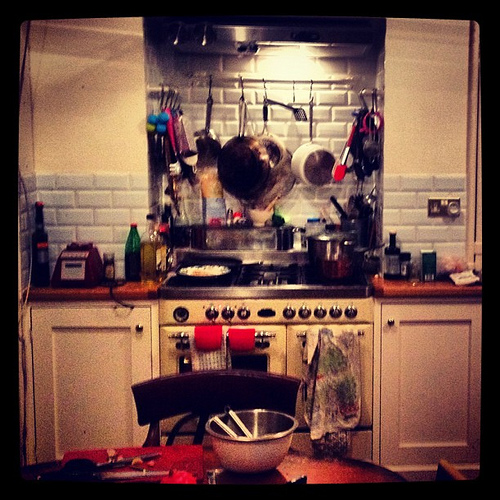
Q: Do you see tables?
A: Yes, there is a table.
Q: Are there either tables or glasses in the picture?
A: Yes, there is a table.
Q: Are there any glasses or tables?
A: Yes, there is a table.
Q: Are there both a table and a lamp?
A: No, there is a table but no lamps.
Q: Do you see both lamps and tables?
A: No, there is a table but no lamps.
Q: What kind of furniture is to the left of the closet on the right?
A: The piece of furniture is a table.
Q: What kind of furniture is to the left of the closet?
A: The piece of furniture is a table.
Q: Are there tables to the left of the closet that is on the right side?
A: Yes, there is a table to the left of the closet.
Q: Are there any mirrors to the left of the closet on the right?
A: No, there is a table to the left of the closet.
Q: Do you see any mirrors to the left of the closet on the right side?
A: No, there is a table to the left of the closet.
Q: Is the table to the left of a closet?
A: Yes, the table is to the left of a closet.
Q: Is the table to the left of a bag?
A: No, the table is to the left of a closet.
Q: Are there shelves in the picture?
A: No, there are no shelves.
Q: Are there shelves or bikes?
A: No, there are no shelves or bikes.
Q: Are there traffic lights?
A: No, there are no traffic lights.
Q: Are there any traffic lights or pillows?
A: No, there are no traffic lights or pillows.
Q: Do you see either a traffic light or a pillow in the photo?
A: No, there are no traffic lights or pillows.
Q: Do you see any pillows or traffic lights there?
A: No, there are no traffic lights or pillows.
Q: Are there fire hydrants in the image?
A: No, there are no fire hydrants.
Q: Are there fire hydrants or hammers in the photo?
A: No, there are no fire hydrants or hammers.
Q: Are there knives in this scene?
A: No, there are no knives.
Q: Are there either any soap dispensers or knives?
A: No, there are no knives or soap dispensers.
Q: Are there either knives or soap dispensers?
A: No, there are no knives or soap dispensers.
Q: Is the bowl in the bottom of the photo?
A: Yes, the bowl is in the bottom of the image.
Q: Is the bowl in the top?
A: No, the bowl is in the bottom of the image.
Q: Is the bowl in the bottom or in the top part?
A: The bowl is in the bottom of the image.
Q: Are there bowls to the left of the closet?
A: Yes, there is a bowl to the left of the closet.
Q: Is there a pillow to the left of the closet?
A: No, there is a bowl to the left of the closet.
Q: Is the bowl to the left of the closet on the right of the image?
A: Yes, the bowl is to the left of the closet.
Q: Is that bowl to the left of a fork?
A: No, the bowl is to the left of the closet.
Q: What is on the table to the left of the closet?
A: The bowl is on the table.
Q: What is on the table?
A: The bowl is on the table.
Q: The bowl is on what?
A: The bowl is on the table.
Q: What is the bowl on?
A: The bowl is on the table.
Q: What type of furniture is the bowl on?
A: The bowl is on the table.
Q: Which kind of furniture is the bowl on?
A: The bowl is on the table.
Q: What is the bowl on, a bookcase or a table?
A: The bowl is on a table.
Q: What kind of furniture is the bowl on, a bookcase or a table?
A: The bowl is on a table.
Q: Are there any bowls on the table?
A: Yes, there is a bowl on the table.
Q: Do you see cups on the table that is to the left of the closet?
A: No, there is a bowl on the table.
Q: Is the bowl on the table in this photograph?
A: Yes, the bowl is on the table.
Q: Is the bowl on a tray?
A: No, the bowl is on the table.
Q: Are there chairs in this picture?
A: Yes, there is a chair.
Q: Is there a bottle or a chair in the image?
A: Yes, there is a chair.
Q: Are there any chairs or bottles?
A: Yes, there is a chair.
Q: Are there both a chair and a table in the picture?
A: Yes, there are both a chair and a table.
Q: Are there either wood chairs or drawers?
A: Yes, there is a wood chair.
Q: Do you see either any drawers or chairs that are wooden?
A: Yes, the chair is wooden.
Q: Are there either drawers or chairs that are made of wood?
A: Yes, the chair is made of wood.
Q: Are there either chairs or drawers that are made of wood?
A: Yes, the chair is made of wood.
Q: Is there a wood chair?
A: Yes, there is a chair that is made of wood.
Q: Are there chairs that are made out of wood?
A: Yes, there is a chair that is made of wood.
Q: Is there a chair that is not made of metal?
A: Yes, there is a chair that is made of wood.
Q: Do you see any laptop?
A: No, there are no laptops.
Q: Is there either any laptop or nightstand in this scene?
A: No, there are no laptops or nightstands.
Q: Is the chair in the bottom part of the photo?
A: Yes, the chair is in the bottom of the image.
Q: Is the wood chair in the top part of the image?
A: No, the chair is in the bottom of the image.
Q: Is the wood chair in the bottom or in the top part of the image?
A: The chair is in the bottom of the image.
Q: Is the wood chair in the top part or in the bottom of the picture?
A: The chair is in the bottom of the image.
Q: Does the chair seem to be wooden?
A: Yes, the chair is wooden.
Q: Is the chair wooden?
A: Yes, the chair is wooden.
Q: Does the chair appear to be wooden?
A: Yes, the chair is wooden.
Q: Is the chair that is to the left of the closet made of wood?
A: Yes, the chair is made of wood.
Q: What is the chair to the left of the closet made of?
A: The chair is made of wood.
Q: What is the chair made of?
A: The chair is made of wood.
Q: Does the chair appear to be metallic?
A: No, the chair is wooden.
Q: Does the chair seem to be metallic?
A: No, the chair is wooden.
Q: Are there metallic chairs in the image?
A: No, there is a chair but it is wooden.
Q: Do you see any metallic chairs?
A: No, there is a chair but it is wooden.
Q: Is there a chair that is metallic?
A: No, there is a chair but it is wooden.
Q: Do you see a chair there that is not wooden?
A: No, there is a chair but it is wooden.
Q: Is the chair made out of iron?
A: No, the chair is made of wood.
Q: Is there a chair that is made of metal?
A: No, there is a chair but it is made of wood.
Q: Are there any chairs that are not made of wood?
A: No, there is a chair but it is made of wood.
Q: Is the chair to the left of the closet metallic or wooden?
A: The chair is wooden.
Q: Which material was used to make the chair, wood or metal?
A: The chair is made of wood.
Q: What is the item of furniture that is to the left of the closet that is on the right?
A: The piece of furniture is a chair.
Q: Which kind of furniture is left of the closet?
A: The piece of furniture is a chair.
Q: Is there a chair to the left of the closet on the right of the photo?
A: Yes, there is a chair to the left of the closet.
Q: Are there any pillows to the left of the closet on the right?
A: No, there is a chair to the left of the closet.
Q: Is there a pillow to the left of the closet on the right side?
A: No, there is a chair to the left of the closet.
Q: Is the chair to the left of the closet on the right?
A: Yes, the chair is to the left of the closet.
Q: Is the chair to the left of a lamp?
A: No, the chair is to the left of the closet.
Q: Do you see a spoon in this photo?
A: Yes, there is a spoon.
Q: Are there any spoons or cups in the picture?
A: Yes, there is a spoon.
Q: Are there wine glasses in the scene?
A: No, there are no wine glasses.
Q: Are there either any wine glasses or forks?
A: No, there are no wine glasses or forks.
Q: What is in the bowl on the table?
A: The spoon is in the bowl.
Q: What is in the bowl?
A: The spoon is in the bowl.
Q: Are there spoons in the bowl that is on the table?
A: Yes, there is a spoon in the bowl.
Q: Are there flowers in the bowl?
A: No, there is a spoon in the bowl.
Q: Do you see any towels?
A: Yes, there is a towel.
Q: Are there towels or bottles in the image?
A: Yes, there is a towel.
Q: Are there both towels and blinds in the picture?
A: No, there is a towel but no blinds.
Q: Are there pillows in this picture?
A: No, there are no pillows.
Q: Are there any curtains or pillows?
A: No, there are no pillows or curtains.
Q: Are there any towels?
A: Yes, there is a towel.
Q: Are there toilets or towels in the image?
A: Yes, there is a towel.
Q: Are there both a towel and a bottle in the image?
A: Yes, there are both a towel and a bottle.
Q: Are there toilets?
A: No, there are no toilets.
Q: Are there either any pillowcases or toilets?
A: No, there are no toilets or pillowcases.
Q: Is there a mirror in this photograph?
A: No, there are no mirrors.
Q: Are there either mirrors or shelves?
A: No, there are no mirrors or shelves.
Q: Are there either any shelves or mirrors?
A: No, there are no mirrors or shelves.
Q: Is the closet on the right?
A: Yes, the closet is on the right of the image.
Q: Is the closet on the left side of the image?
A: No, the closet is on the right of the image.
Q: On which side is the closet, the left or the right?
A: The closet is on the right of the image.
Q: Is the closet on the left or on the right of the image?
A: The closet is on the right of the image.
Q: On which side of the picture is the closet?
A: The closet is on the right of the image.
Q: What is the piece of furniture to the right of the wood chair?
A: The piece of furniture is a closet.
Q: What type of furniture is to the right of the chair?
A: The piece of furniture is a closet.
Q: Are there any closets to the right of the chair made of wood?
A: Yes, there is a closet to the right of the chair.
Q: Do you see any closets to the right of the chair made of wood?
A: Yes, there is a closet to the right of the chair.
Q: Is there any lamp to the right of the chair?
A: No, there is a closet to the right of the chair.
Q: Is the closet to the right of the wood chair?
A: Yes, the closet is to the right of the chair.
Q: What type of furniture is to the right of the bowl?
A: The piece of furniture is a closet.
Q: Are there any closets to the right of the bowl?
A: Yes, there is a closet to the right of the bowl.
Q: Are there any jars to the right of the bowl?
A: No, there is a closet to the right of the bowl.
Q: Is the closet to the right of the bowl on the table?
A: Yes, the closet is to the right of the bowl.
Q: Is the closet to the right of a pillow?
A: No, the closet is to the right of the bowl.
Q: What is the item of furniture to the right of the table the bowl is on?
A: The piece of furniture is a closet.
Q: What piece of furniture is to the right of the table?
A: The piece of furniture is a closet.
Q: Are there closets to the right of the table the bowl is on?
A: Yes, there is a closet to the right of the table.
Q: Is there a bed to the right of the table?
A: No, there is a closet to the right of the table.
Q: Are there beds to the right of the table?
A: No, there is a closet to the right of the table.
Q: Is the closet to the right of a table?
A: Yes, the closet is to the right of a table.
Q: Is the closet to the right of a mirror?
A: No, the closet is to the right of a table.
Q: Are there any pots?
A: Yes, there is a pot.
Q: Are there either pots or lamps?
A: Yes, there is a pot.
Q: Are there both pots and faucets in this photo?
A: No, there is a pot but no faucets.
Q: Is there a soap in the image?
A: No, there are no soaps.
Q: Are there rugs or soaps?
A: No, there are no soaps or rugs.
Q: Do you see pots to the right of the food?
A: Yes, there is a pot to the right of the food.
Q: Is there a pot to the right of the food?
A: Yes, there is a pot to the right of the food.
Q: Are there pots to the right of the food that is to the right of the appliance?
A: Yes, there is a pot to the right of the food.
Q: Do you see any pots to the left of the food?
A: No, the pot is to the right of the food.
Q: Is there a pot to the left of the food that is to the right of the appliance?
A: No, the pot is to the right of the food.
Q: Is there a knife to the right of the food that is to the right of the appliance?
A: No, there is a pot to the right of the food.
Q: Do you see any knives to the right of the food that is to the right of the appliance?
A: No, there is a pot to the right of the food.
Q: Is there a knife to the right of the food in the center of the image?
A: No, there is a pot to the right of the food.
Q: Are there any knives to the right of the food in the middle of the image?
A: No, there is a pot to the right of the food.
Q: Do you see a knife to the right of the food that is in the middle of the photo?
A: No, there is a pot to the right of the food.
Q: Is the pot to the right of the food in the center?
A: Yes, the pot is to the right of the food.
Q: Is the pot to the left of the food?
A: No, the pot is to the right of the food.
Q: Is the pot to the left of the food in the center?
A: No, the pot is to the right of the food.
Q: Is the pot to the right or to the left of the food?
A: The pot is to the right of the food.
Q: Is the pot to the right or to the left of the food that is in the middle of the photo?
A: The pot is to the right of the food.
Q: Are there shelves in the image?
A: No, there are no shelves.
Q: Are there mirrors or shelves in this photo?
A: No, there are no shelves or mirrors.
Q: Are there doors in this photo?
A: Yes, there is a door.